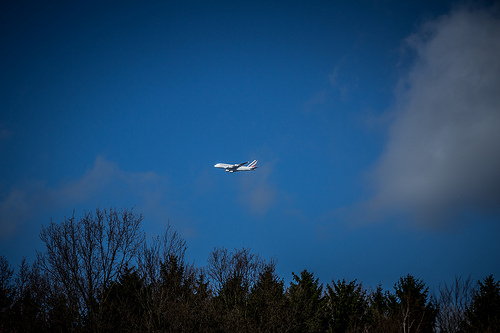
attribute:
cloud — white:
[362, 1, 496, 233]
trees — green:
[14, 206, 494, 326]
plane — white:
[207, 152, 259, 179]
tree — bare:
[35, 211, 141, 331]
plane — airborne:
[212, 158, 260, 174]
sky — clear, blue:
[2, 2, 496, 309]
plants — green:
[3, 208, 497, 330]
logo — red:
[247, 158, 258, 168]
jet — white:
[210, 159, 261, 173]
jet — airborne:
[216, 158, 259, 178]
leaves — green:
[281, 266, 327, 331]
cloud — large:
[346, 3, 496, 227]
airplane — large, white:
[213, 159, 258, 172]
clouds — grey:
[3, 2, 498, 248]